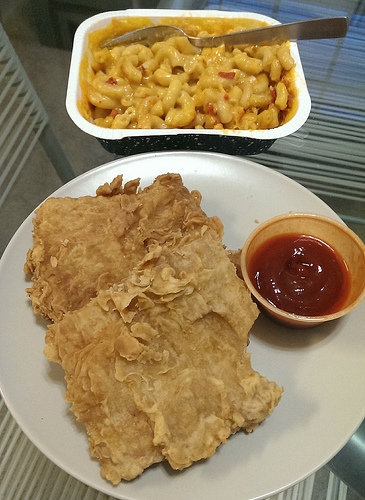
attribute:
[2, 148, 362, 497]
white plate — round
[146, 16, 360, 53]
fork — metal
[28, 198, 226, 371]
chicken — fried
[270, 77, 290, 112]
macaroni noodle — cheesy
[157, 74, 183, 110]
macaroni noodle — cheesy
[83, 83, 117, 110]
macaroni noodle — cheesy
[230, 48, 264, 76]
macaroni noodle — cheesy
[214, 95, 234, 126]
macaroni noodle — cheesy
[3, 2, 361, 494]
table — glass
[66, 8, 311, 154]
bowl — paper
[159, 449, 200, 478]
chicken — breaded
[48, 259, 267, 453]
meat — crispy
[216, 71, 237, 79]
flake — red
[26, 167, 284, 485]
breast — large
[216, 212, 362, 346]
cup — plastic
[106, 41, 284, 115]
mac&cheese — cheesy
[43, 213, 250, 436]
chicken — fried